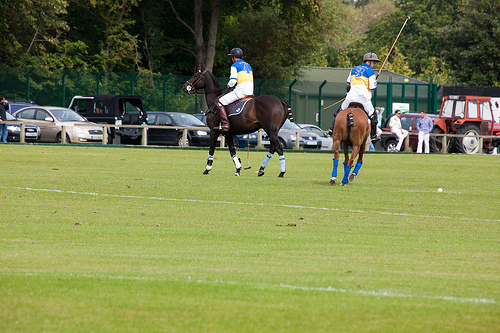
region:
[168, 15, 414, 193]
the men are on horsebacks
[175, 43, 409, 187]
the men are playin polo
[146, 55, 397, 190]
the men have the same uniform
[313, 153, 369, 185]
the horse has blue socks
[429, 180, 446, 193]
the ball is white in colour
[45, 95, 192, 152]
cars are parked on the side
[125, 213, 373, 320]
the lawn is green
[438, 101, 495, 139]
the tractor is red in colour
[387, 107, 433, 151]
men are seated on a fence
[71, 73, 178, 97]
the fence is green in colour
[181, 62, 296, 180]
dark brown horse walking in grassy field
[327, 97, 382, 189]
light brown horse walking in grassy green field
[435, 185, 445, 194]
small white polo ball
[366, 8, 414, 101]
long thin polo mallet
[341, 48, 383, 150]
polo player wearing white blue and yellow outfit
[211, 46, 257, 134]
polo player wearing white blue and yellow outfit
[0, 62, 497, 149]
long green fence around field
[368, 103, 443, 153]
people sitting on railing next to field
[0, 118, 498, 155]
short gray railing around field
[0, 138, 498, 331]
large wide green grassy field with white chalk lines on it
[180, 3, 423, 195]
two polo players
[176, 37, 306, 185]
a polo player seated on his horse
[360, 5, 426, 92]
the mallet of a polo player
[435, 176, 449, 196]
the ball used to play polo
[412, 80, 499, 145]
a red tractor on the side of the field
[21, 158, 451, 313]
lines painted on a polo field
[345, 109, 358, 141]
tied and braided tail of a horse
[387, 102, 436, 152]
people watching polo from the sidelines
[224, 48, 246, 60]
polo player wearing a helmet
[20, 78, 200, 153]
vehicles in the parking lot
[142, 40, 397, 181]
The players are on horses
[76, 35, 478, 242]
They are playing cricket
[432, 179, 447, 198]
The ball is white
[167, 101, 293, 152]
The horse is dark brown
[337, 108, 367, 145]
The horse is light brown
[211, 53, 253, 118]
The uniform is blue and white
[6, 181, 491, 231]
There are white lines on the field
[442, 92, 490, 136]
The truck is red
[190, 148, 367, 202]
The horses have shoes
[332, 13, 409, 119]
Holding a cricket bat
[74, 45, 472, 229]
these people are playing polo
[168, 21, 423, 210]
these people are on the same team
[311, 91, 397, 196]
this horse is light brown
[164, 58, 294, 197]
this horse is dark brown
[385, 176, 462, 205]
this is a ball on the ground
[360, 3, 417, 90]
this is a long stick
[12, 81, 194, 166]
cars in the background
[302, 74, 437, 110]
a fence in the area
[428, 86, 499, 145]
a red truck in the area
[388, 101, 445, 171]
two people in talking